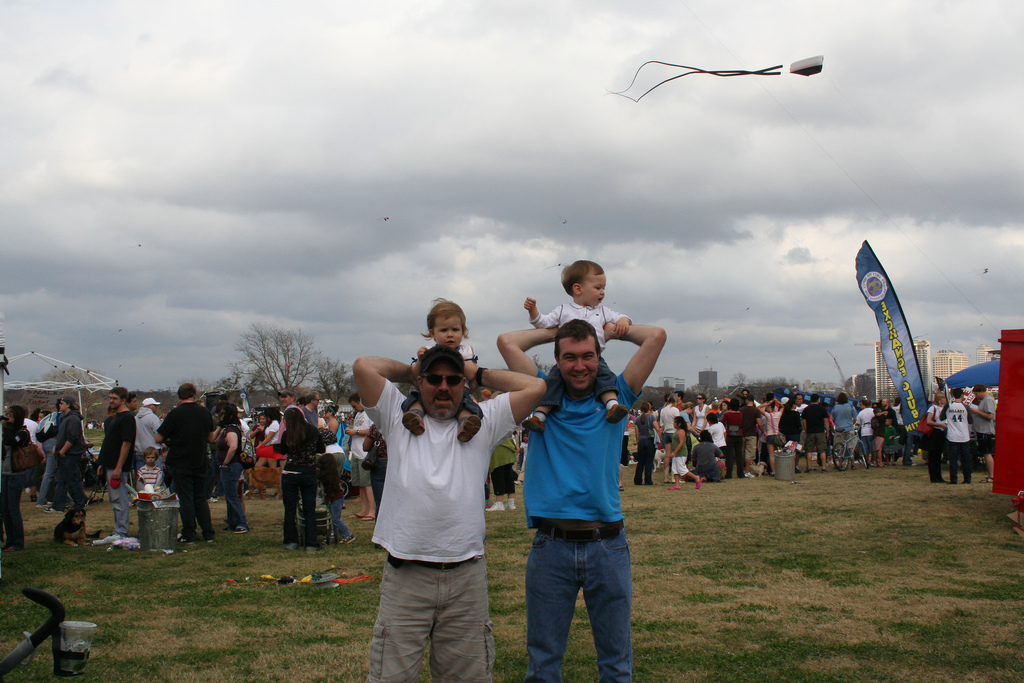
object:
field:
[2, 390, 1023, 680]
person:
[273, 407, 328, 551]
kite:
[605, 54, 824, 103]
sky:
[0, 0, 1023, 398]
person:
[939, 387, 973, 484]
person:
[668, 415, 704, 489]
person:
[92, 386, 135, 547]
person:
[44, 395, 91, 514]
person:
[871, 410, 887, 468]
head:
[416, 351, 466, 419]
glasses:
[425, 372, 444, 385]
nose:
[438, 375, 451, 391]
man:
[351, 345, 549, 682]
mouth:
[433, 394, 455, 405]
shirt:
[360, 378, 526, 564]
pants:
[364, 554, 506, 682]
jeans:
[520, 521, 639, 683]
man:
[495, 320, 668, 682]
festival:
[0, 0, 1023, 682]